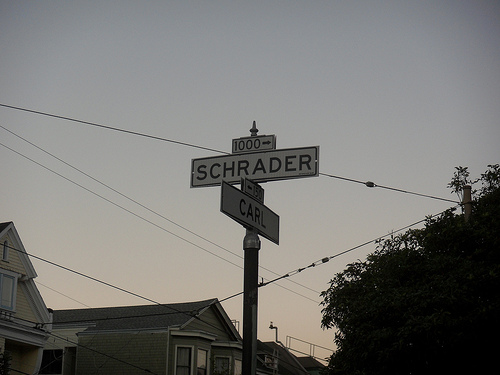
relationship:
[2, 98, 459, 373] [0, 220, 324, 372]
telephone wires going to houses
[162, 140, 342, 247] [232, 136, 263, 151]
schrader street block numbers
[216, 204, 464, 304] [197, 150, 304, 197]
telephone wires behind sign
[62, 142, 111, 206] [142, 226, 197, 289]
these are wires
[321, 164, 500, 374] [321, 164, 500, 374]
hedge tree has green hedge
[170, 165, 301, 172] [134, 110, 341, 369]
street sign for schrader and carl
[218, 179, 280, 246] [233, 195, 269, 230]
street sign with text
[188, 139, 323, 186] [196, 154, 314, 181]
street sign with street sign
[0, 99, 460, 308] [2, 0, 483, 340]
power lines on sky